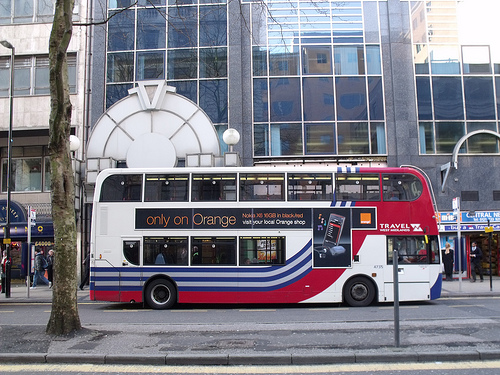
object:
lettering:
[465, 211, 499, 222]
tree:
[43, 2, 90, 338]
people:
[0, 248, 54, 291]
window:
[144, 172, 190, 202]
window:
[190, 171, 237, 202]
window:
[236, 172, 285, 202]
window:
[286, 170, 334, 202]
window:
[335, 173, 380, 201]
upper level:
[92, 165, 435, 211]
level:
[92, 165, 434, 202]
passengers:
[143, 238, 251, 265]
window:
[144, 236, 189, 267]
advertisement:
[135, 207, 312, 232]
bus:
[88, 164, 446, 310]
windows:
[99, 174, 143, 202]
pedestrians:
[442, 241, 485, 282]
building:
[0, 0, 499, 283]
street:
[2, 277, 500, 372]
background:
[2, 196, 94, 298]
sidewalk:
[0, 276, 499, 303]